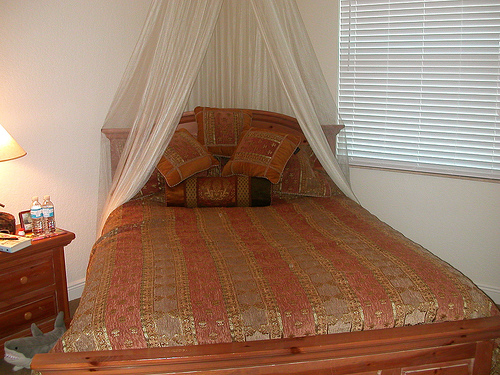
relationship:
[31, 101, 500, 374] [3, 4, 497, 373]
bed in bedroom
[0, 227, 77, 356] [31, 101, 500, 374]
night stand next to bed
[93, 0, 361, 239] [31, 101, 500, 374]
mosquito net over bed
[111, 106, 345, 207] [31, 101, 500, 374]
pillows on bed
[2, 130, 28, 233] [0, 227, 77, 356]
lamp on top of night stand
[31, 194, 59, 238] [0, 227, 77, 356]
water bottles on top of night stand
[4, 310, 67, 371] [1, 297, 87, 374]
whale on floor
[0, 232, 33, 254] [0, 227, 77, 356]
book on top of night stand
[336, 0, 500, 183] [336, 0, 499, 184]
blinds on blinds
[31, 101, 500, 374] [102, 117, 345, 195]
bed has frame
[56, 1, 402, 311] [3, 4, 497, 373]
corner in bedroom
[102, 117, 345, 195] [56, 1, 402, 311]
frame in corner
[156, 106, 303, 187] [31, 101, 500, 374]
pillows on bed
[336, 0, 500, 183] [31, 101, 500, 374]
blinds near bed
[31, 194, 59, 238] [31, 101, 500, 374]
water bottles next to bed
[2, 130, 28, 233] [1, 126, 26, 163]
lamp has shade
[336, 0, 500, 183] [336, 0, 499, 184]
blinds over blinds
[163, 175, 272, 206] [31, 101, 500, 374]
pillow on bed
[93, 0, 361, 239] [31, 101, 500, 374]
mosquito net behind bed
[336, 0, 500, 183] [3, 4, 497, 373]
blinds in bedroom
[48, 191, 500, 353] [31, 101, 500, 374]
comforter on bed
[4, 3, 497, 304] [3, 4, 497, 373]
wall in bedroom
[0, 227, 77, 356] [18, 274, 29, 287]
night stand has knob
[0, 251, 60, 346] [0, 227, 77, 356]
drawers on night stand